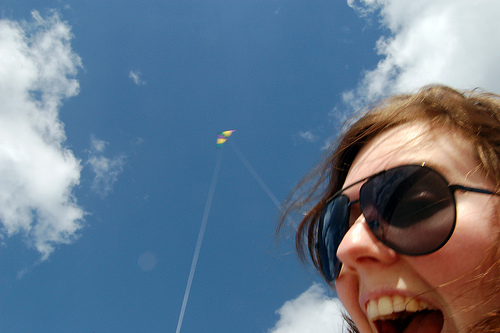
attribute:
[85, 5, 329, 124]
sky — blue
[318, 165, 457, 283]
glasses — black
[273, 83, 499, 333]
woman — smiling, smling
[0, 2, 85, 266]
cloud — white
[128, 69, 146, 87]
cloud — small, tiny